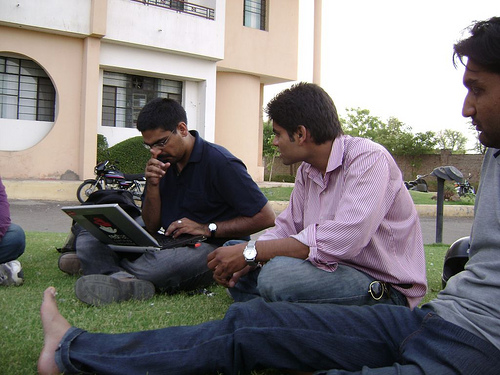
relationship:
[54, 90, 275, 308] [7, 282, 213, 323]
man sit in grass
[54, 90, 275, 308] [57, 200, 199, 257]
man has laptop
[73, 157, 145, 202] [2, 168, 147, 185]
motor bike in background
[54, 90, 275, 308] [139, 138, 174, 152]
man has sunglasses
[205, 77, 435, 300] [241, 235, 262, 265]
man wears watch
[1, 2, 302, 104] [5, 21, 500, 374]
building behind people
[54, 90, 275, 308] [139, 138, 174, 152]
man wears glasses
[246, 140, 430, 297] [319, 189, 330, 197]
shirt has button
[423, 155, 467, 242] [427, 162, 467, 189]
light solar powered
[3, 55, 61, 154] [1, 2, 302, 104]
window on side of building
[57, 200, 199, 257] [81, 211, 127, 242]
laptop has sticker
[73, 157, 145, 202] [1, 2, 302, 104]
motorcycle front of building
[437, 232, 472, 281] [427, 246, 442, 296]
helmet laying on grass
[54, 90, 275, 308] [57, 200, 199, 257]
man using laptop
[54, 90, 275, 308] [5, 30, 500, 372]
man sitting outside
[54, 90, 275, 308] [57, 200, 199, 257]
man looks at laptop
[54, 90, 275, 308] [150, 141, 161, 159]
man itches nose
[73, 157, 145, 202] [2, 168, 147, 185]
motorcycle in background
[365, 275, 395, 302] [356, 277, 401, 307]
sunglasses in pocket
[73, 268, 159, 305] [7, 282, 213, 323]
shoe in grass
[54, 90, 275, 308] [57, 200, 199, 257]
man typing on laptop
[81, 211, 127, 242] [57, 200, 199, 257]
sticker on top of laptop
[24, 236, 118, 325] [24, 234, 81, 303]
ground covered with grass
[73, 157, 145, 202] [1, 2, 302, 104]
motor bike in front of building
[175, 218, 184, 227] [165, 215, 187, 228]
ring on finger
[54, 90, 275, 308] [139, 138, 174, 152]
man has glasses